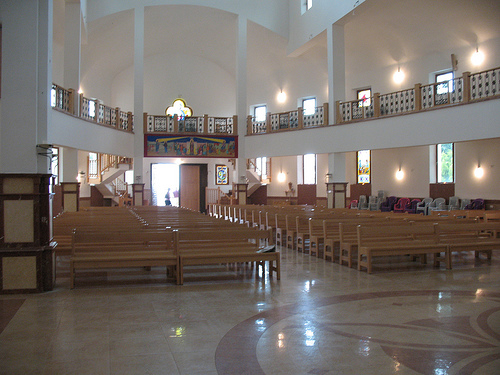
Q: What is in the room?
A: Wooden.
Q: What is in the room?
A: Windows.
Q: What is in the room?
A: Floor.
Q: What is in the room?
A: Deisgn.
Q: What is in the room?
A: Lights.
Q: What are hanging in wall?
A: Lights.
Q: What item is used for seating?
A: A bench.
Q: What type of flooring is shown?
A: A tile.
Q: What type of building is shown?
A: A church.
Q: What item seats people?
A: A bench.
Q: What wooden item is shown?
A: A bench.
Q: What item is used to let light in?
A: A window.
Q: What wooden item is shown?
A: A bench.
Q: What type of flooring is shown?
A: Tile.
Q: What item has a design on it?
A: A floor.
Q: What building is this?
A: Church.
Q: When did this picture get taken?
A: It was taken in the day time.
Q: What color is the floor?
A: The floor is tan.